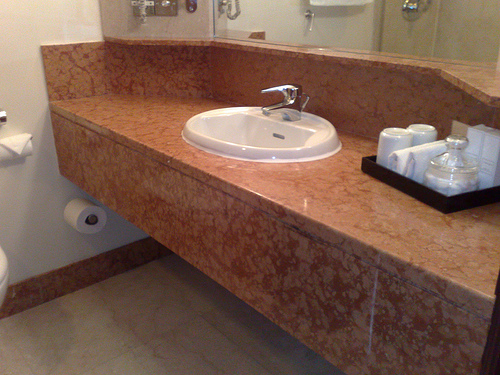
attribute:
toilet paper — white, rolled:
[0, 132, 35, 163]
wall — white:
[1, 0, 149, 285]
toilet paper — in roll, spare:
[63, 197, 108, 237]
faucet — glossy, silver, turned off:
[259, 84, 311, 123]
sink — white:
[182, 106, 342, 165]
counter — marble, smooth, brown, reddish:
[49, 97, 499, 324]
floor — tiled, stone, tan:
[1, 252, 345, 375]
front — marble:
[48, 109, 499, 374]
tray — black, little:
[360, 154, 499, 213]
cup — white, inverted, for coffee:
[406, 123, 437, 147]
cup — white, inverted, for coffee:
[376, 128, 412, 169]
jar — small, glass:
[423, 134, 482, 198]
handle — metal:
[87, 215, 96, 223]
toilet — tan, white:
[1, 249, 12, 307]